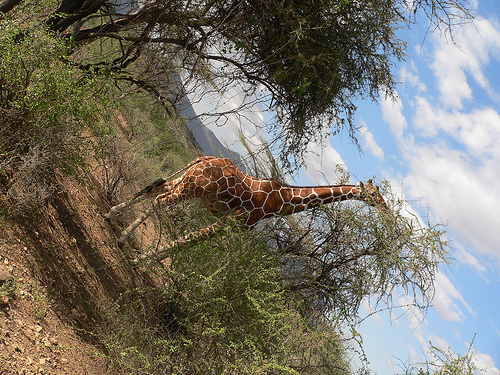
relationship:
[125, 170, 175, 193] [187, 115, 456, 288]
tail on giraffe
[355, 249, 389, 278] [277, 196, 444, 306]
leaves from tree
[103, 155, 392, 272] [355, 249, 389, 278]
giraffe eating leaves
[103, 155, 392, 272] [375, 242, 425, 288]
giraffe eating leaves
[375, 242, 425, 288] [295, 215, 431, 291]
leaves from tree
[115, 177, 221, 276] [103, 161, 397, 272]
legs of giraffe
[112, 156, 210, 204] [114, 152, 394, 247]
tail of giraffe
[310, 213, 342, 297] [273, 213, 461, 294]
branches on tree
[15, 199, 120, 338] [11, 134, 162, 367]
shadows on ground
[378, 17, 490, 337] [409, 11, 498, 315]
sky behind clouds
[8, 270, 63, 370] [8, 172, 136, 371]
rocks on ground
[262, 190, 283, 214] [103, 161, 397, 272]
spot on giraffe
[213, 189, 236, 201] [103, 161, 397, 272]
spot on giraffe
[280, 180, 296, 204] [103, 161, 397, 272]
spot on giraffe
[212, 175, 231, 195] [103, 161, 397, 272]
spot on giraffe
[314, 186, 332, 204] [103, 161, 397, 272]
spot on giraffe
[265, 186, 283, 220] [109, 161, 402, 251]
spot on giraffe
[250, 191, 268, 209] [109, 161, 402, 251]
spot on giraffe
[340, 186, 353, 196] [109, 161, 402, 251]
spot on giraffe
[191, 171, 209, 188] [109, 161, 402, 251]
spot on giraffe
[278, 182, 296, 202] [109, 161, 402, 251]
spot on giraffe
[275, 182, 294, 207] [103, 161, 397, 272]
spot on giraffe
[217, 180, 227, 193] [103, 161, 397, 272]
spot on giraffe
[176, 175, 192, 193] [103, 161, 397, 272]
spot on giraffe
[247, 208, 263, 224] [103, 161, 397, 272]
spot on giraffe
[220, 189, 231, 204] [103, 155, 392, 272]
spot on giraffe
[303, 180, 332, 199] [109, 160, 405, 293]
spot on giraffe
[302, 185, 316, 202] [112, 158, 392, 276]
spot on giraffe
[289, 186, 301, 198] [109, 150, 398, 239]
spot on giraffe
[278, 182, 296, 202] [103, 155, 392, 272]
spot on giraffe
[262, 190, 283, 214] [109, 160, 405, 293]
spot on giraffe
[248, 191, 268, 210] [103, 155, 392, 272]
spot on giraffe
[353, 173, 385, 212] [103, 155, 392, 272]
head of a giraffe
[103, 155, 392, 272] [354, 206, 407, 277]
giraffe eating leaves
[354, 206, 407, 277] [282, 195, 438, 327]
leaves from tree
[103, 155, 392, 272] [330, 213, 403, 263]
giraffe eating leaves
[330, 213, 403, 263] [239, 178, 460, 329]
leaves from tree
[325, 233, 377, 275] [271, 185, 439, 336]
leaves from tree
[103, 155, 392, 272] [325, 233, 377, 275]
giraffe eating leaves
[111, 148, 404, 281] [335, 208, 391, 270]
giraffe eating leaves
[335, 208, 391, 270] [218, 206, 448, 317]
leaves from tree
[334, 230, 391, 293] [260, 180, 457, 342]
leaves from tree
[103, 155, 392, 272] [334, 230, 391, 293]
giraffe eating leaves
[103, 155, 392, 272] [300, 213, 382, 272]
giraffe eating leaves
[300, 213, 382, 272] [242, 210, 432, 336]
leaves from tree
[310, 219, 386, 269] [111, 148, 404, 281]
leaves from giraffe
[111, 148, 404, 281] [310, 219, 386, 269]
giraffe eating leaves